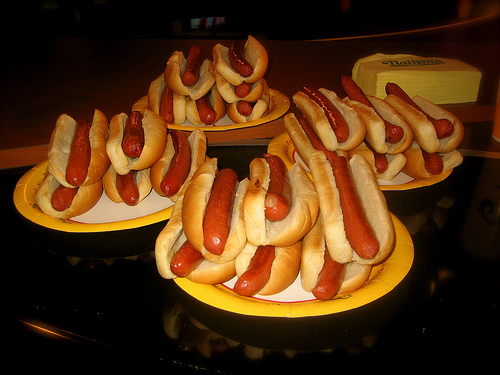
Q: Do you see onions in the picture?
A: No, there are no onions.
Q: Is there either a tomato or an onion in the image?
A: No, there are no onions or tomatoes.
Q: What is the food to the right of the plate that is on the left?
A: The food is a bun.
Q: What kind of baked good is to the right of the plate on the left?
A: The food is a bun.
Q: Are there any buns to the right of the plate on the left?
A: Yes, there is a bun to the right of the plate.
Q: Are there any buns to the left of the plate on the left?
A: No, the bun is to the right of the plate.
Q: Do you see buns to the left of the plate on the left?
A: No, the bun is to the right of the plate.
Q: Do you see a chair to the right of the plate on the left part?
A: No, there is a bun to the right of the plate.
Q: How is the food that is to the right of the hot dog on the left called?
A: The food is a bun.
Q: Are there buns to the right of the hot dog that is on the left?
A: Yes, there is a bun to the right of the hot dog.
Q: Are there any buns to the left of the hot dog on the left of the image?
A: No, the bun is to the right of the hot dog.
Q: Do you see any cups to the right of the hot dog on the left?
A: No, there is a bun to the right of the hot dog.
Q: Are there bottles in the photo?
A: No, there are no bottles.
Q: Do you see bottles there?
A: No, there are no bottles.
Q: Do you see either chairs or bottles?
A: No, there are no bottles or chairs.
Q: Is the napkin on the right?
A: Yes, the napkin is on the right of the image.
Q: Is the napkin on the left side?
A: No, the napkin is on the right of the image.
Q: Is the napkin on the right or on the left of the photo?
A: The napkin is on the right of the image.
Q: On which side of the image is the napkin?
A: The napkin is on the right of the image.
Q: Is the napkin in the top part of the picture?
A: Yes, the napkin is in the top of the image.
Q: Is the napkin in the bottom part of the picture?
A: No, the napkin is in the top of the image.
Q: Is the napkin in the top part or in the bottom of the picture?
A: The napkin is in the top of the image.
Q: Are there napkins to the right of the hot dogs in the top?
A: Yes, there is a napkin to the right of the hot dogs.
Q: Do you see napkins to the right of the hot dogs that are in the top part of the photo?
A: Yes, there is a napkin to the right of the hot dogs.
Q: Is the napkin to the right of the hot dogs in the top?
A: Yes, the napkin is to the right of the hot dogs.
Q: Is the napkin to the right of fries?
A: No, the napkin is to the right of the hot dogs.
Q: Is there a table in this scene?
A: Yes, there is a table.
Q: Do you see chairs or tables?
A: Yes, there is a table.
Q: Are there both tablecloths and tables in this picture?
A: No, there is a table but no tablecloths.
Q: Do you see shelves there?
A: No, there are no shelves.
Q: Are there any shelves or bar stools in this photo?
A: No, there are no shelves or bar stools.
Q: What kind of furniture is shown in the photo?
A: The furniture is a table.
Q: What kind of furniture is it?
A: The piece of furniture is a table.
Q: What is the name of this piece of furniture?
A: This is a table.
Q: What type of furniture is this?
A: This is a table.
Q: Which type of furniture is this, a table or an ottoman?
A: This is a table.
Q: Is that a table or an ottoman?
A: That is a table.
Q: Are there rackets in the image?
A: No, there are no rackets.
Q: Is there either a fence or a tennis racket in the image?
A: No, there are no rackets or fences.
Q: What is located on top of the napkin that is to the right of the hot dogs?
A: The logo is on top of the napkin.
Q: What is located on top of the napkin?
A: The logo is on top of the napkin.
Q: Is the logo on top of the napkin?
A: Yes, the logo is on top of the napkin.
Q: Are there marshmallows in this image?
A: No, there are no marshmallows.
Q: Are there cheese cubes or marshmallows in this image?
A: No, there are no marshmallows or cheese cubes.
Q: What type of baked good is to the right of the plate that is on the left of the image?
A: The food is a bun.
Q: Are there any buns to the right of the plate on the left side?
A: Yes, there is a bun to the right of the plate.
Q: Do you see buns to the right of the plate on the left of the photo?
A: Yes, there is a bun to the right of the plate.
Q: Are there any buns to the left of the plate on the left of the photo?
A: No, the bun is to the right of the plate.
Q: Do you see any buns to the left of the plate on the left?
A: No, the bun is to the right of the plate.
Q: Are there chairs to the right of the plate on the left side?
A: No, there is a bun to the right of the plate.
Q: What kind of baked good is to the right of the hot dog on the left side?
A: The food is a bun.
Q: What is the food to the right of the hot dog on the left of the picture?
A: The food is a bun.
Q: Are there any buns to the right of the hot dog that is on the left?
A: Yes, there is a bun to the right of the hot dog.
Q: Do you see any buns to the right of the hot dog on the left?
A: Yes, there is a bun to the right of the hot dog.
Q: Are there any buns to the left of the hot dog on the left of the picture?
A: No, the bun is to the right of the hot dog.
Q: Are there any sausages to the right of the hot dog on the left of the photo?
A: No, there is a bun to the right of the hot dog.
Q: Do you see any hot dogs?
A: Yes, there is a hot dog.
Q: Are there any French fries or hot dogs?
A: Yes, there is a hot dog.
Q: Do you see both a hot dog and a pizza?
A: No, there is a hot dog but no pizzas.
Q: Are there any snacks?
A: No, there are no snacks.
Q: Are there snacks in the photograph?
A: No, there are no snacks.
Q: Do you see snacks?
A: No, there are no snacks.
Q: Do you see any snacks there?
A: No, there are no snacks.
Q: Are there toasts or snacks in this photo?
A: No, there are no snacks or toasts.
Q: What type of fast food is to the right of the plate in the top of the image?
A: The food is a hot dog.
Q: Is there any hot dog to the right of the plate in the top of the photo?
A: Yes, there is a hot dog to the right of the plate.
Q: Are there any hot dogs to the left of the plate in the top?
A: No, the hot dog is to the right of the plate.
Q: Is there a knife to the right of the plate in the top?
A: No, there is a hot dog to the right of the plate.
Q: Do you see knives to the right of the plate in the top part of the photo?
A: No, there is a hot dog to the right of the plate.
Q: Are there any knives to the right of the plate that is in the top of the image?
A: No, there is a hot dog to the right of the plate.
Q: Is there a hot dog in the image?
A: Yes, there is a hot dog.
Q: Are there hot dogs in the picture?
A: Yes, there is a hot dog.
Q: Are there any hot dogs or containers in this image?
A: Yes, there is a hot dog.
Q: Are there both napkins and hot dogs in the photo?
A: Yes, there are both a hot dog and a napkin.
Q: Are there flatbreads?
A: No, there are no flatbreads.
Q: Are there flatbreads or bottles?
A: No, there are no flatbreads or bottles.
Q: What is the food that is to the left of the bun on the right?
A: The food is a hot dog.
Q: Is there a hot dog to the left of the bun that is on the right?
A: Yes, there is a hot dog to the left of the bun.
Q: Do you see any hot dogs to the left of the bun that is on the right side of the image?
A: Yes, there is a hot dog to the left of the bun.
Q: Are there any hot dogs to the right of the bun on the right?
A: No, the hot dog is to the left of the bun.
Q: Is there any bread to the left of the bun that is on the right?
A: No, there is a hot dog to the left of the bun.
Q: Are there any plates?
A: Yes, there is a plate.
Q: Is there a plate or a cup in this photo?
A: Yes, there is a plate.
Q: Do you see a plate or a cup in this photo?
A: Yes, there is a plate.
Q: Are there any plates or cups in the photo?
A: Yes, there is a plate.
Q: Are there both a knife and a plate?
A: No, there is a plate but no knives.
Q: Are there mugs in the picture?
A: No, there are no mugs.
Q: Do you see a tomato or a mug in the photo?
A: No, there are no mugs or tomatoes.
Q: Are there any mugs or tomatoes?
A: No, there are no mugs or tomatoes.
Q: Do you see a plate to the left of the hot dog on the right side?
A: Yes, there is a plate to the left of the hot dog.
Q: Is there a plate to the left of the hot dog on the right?
A: Yes, there is a plate to the left of the hot dog.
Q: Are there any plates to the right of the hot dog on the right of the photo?
A: No, the plate is to the left of the hot dog.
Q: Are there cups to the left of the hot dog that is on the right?
A: No, there is a plate to the left of the hot dog.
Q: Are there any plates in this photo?
A: Yes, there is a plate.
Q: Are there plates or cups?
A: Yes, there is a plate.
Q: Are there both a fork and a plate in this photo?
A: No, there is a plate but no forks.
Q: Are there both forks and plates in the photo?
A: No, there is a plate but no forks.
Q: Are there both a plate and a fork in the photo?
A: No, there is a plate but no forks.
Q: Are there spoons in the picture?
A: No, there are no spoons.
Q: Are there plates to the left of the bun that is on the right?
A: Yes, there is a plate to the left of the bun.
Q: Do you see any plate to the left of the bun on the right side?
A: Yes, there is a plate to the left of the bun.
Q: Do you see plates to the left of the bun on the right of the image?
A: Yes, there is a plate to the left of the bun.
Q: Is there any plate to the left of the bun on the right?
A: Yes, there is a plate to the left of the bun.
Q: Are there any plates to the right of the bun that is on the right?
A: No, the plate is to the left of the bun.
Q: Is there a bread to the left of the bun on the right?
A: No, there is a plate to the left of the bun.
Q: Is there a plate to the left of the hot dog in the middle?
A: Yes, there is a plate to the left of the hot dog.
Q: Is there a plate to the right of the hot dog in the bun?
A: No, the plate is to the left of the hot dog.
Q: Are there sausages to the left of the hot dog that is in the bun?
A: No, there is a plate to the left of the hot dog.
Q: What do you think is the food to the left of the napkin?
A: The food is hot dogs.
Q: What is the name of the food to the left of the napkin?
A: The food is hot dogs.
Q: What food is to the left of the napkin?
A: The food is hot dogs.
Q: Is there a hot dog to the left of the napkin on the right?
A: Yes, there are hot dogs to the left of the napkin.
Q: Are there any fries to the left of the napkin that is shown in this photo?
A: No, there are hot dogs to the left of the napkin.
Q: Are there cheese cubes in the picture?
A: No, there are no cheese cubes.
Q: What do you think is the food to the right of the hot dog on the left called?
A: The food is a bun.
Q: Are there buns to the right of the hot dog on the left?
A: Yes, there is a bun to the right of the hot dog.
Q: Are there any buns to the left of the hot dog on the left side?
A: No, the bun is to the right of the hot dog.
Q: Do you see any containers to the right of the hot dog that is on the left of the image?
A: No, there is a bun to the right of the hot dog.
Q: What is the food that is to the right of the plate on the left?
A: The food is a bun.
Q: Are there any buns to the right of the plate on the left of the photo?
A: Yes, there is a bun to the right of the plate.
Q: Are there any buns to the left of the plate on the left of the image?
A: No, the bun is to the right of the plate.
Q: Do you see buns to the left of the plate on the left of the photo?
A: No, the bun is to the right of the plate.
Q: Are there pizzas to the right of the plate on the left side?
A: No, there is a bun to the right of the plate.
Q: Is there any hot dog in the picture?
A: Yes, there is a hot dog.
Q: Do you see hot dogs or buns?
A: Yes, there is a hot dog.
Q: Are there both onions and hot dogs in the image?
A: No, there is a hot dog but no onions.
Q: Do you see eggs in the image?
A: No, there are no eggs.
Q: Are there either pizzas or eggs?
A: No, there are no eggs or pizzas.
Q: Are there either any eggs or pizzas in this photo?
A: No, there are no eggs or pizzas.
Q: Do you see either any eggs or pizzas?
A: No, there are no eggs or pizzas.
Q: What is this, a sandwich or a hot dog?
A: This is a hot dog.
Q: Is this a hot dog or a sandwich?
A: This is a hot dog.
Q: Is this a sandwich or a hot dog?
A: This is a hot dog.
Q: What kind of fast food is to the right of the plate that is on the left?
A: The food is a hot dog.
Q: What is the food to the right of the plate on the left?
A: The food is a hot dog.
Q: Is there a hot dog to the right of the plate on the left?
A: Yes, there is a hot dog to the right of the plate.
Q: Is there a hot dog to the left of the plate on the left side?
A: No, the hot dog is to the right of the plate.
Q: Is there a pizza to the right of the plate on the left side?
A: No, there is a hot dog to the right of the plate.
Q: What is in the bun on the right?
A: The hot dog is in the bun.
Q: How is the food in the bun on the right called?
A: The food is a hot dog.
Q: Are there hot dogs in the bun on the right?
A: Yes, there is a hot dog in the bun.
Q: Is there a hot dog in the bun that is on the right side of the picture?
A: Yes, there is a hot dog in the bun.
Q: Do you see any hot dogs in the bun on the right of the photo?
A: Yes, there is a hot dog in the bun.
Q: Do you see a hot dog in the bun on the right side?
A: Yes, there is a hot dog in the bun.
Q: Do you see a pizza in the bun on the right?
A: No, there is a hot dog in the bun.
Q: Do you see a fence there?
A: No, there are no fences.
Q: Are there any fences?
A: No, there are no fences.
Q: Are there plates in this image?
A: Yes, there is a plate.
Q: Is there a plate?
A: Yes, there is a plate.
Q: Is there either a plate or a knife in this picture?
A: Yes, there is a plate.